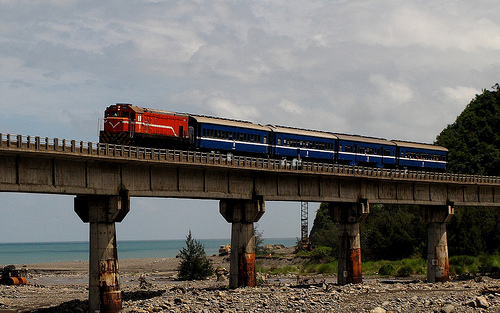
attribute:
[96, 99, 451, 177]
train — blue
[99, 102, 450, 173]
train — blue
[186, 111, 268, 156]
passenger cars — blue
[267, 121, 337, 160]
passenger cars — blue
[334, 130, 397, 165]
passenger cars — blue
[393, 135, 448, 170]
passenger cars — blue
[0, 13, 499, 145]
clouds — white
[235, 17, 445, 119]
clouds — white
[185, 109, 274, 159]
car — blue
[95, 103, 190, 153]
engine — red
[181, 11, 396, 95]
clouds — white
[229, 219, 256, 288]
pillar — steel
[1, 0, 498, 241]
grey sky — cloudy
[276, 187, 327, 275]
tower — radio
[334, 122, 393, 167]
train — blue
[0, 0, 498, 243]
sky — cloudy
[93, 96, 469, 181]
train — blue, long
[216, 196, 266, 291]
post — metal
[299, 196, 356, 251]
tower — metal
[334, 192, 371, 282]
post — metal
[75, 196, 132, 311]
post — metal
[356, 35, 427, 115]
clouds — white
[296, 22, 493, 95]
sky — blue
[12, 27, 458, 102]
sky — blue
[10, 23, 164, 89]
sky — blue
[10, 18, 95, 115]
sky — blue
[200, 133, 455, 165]
stripe — white